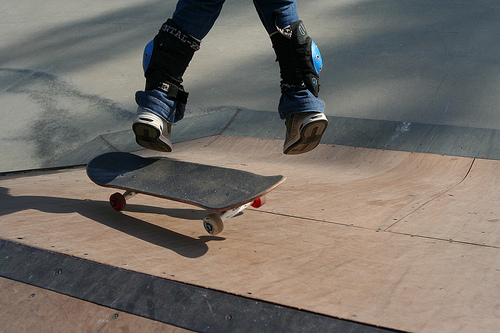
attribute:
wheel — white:
[189, 209, 246, 248]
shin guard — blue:
[267, 17, 319, 98]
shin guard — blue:
[143, 14, 198, 114]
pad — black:
[132, 29, 209, 95]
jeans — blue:
[137, 0, 477, 199]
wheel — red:
[243, 187, 278, 227]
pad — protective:
[265, 16, 335, 100]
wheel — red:
[251, 198, 271, 207]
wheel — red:
[200, 210, 222, 235]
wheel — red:
[106, 187, 127, 212]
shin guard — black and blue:
[268, 15, 327, 98]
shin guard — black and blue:
[133, 27, 210, 109]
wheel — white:
[202, 211, 224, 236]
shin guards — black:
[276, 20, 322, 99]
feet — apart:
[112, 102, 344, 157]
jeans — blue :
[124, 1, 363, 141]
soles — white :
[130, 122, 172, 153]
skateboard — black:
[83, 148, 287, 236]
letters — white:
[160, 22, 201, 50]